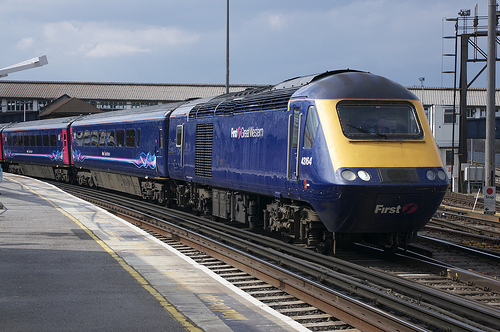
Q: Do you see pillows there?
A: No, there are no pillows.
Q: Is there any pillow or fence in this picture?
A: No, there are no pillows or fences.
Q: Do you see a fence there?
A: No, there are no fences.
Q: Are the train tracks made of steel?
A: Yes, the train tracks are made of steel.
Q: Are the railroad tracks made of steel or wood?
A: The railroad tracks are made of steel.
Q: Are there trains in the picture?
A: Yes, there is a train.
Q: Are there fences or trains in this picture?
A: Yes, there is a train.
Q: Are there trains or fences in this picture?
A: Yes, there is a train.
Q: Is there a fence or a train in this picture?
A: Yes, there is a train.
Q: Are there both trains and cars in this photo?
A: Yes, there are both a train and a car.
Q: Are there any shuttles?
A: No, there are no shuttles.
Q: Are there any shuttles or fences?
A: No, there are no shuttles or fences.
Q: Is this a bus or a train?
A: This is a train.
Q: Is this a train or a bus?
A: This is a train.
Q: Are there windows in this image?
A: Yes, there are windows.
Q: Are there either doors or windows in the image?
A: Yes, there are windows.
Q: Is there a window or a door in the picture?
A: Yes, there are windows.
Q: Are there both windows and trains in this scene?
A: Yes, there are both windows and a train.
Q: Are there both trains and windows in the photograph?
A: Yes, there are both windows and a train.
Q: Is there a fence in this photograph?
A: No, there are no fences.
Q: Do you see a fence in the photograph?
A: No, there are no fences.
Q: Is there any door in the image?
A: Yes, there is a door.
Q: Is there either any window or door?
A: Yes, there is a door.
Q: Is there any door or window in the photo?
A: Yes, there is a door.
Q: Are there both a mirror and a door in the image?
A: No, there is a door but no mirrors.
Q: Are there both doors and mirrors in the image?
A: No, there is a door but no mirrors.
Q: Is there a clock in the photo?
A: No, there are no clocks.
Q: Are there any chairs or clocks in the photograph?
A: No, there are no clocks or chairs.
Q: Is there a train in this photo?
A: Yes, there is a train.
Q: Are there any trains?
A: Yes, there is a train.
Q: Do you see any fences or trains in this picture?
A: Yes, there is a train.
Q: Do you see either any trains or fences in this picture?
A: Yes, there is a train.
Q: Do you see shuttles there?
A: No, there are no shuttles.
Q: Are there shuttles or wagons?
A: No, there are no shuttles or wagons.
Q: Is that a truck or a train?
A: That is a train.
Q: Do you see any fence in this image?
A: No, there are no fences.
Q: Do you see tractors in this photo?
A: No, there are no tractors.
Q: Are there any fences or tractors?
A: No, there are no tractors or fences.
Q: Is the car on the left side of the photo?
A: Yes, the car is on the left of the image.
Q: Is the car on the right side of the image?
A: No, the car is on the left of the image.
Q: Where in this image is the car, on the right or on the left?
A: The car is on the left of the image.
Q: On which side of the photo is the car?
A: The car is on the left of the image.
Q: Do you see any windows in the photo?
A: Yes, there is a window.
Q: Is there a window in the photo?
A: Yes, there is a window.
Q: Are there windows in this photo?
A: Yes, there is a window.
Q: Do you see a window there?
A: Yes, there is a window.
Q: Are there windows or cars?
A: Yes, there is a window.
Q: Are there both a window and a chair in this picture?
A: No, there is a window but no chairs.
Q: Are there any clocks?
A: No, there are no clocks.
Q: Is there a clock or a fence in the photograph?
A: No, there are no clocks or fences.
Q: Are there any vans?
A: No, there are no vans.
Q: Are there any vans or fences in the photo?
A: No, there are no vans or fences.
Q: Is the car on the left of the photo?
A: Yes, the car is on the left of the image.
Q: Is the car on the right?
A: No, the car is on the left of the image.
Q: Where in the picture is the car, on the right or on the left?
A: The car is on the left of the image.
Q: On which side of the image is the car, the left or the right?
A: The car is on the left of the image.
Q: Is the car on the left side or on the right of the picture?
A: The car is on the left of the image.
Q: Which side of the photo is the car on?
A: The car is on the left of the image.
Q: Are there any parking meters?
A: No, there are no parking meters.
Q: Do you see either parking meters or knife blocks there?
A: No, there are no parking meters or knife blocks.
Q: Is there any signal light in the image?
A: No, there are no traffic lights.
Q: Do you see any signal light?
A: No, there are no traffic lights.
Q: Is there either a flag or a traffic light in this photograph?
A: No, there are no traffic lights or flags.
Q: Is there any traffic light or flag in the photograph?
A: No, there are no traffic lights or flags.